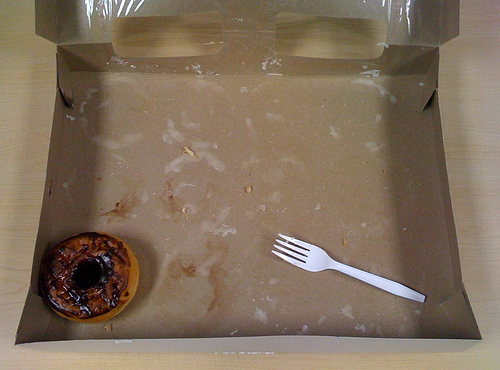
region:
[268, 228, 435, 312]
white plastic fork in box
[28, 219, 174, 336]
doughnut sitting in box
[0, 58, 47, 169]
brown wooden table top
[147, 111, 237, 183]
white sugar in bottom of box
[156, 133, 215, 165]
doughnut crumbs laying in bottom of box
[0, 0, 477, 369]
doughnut box sitting on table top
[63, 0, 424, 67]
clear plastic wrap on top of doughnut box lid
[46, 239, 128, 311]
chocolate on top of doughnut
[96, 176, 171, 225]
chocolate smear on bottom of box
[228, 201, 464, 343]
white plastic fork laying in doughnut box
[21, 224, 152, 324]
chocolate doughnut sitting in box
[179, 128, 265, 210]
doughnut crumbs in box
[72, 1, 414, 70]
clear plastic wrap on the lid of box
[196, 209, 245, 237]
glazed sugar on bottom of box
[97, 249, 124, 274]
chocolate glaze on top of doughnut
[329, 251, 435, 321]
white plastic handle on fork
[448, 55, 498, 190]
brown wooden table top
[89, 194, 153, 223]
chocolate smudge on bottom of box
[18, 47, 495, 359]
doughnut box sitting on table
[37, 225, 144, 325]
a donut in a box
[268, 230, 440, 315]
a fork in a box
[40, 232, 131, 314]
chocolate on a donut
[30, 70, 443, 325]
one donut left in a box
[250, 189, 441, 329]
a single fork in a box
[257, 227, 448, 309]
a plastic fork in a box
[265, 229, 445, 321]
a white fork in a box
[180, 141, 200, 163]
a donut crumb in a box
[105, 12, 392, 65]
windows in a box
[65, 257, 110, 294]
the center of a donut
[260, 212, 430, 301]
fork sitting in the box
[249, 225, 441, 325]
the fork is white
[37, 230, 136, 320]
doughnut sitting in the box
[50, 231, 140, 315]
doughnut has black frosting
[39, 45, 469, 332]
box sitting on the table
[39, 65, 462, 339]
box made of cardboard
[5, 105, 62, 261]
table under the box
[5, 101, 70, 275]
table is tan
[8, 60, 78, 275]
table made of wood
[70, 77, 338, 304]
smudges on the box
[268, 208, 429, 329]
white fork in a box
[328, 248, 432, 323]
white handle of fork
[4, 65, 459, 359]
large card board box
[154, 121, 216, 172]
white marks on box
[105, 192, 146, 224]
brown marks on box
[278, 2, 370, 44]
clear plastic on box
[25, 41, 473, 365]
cardboard bottom of box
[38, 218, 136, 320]
donut in bottom left